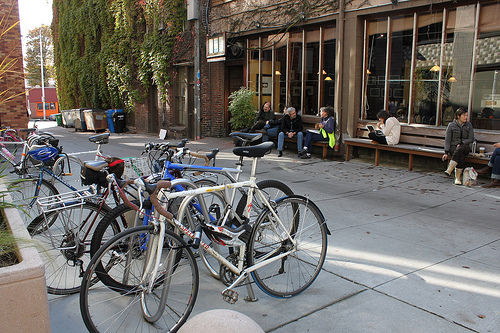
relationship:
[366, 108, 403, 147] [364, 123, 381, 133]
people with laptop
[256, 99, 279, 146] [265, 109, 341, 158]
people on bench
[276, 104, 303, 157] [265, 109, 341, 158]
people on bench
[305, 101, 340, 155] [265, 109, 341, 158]
people on bench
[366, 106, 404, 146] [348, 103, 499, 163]
people on bench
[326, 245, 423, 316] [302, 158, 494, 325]
crack on sidewalk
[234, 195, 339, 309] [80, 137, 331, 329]
wheel on bike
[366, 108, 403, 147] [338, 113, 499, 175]
people on bench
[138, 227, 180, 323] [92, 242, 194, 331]
bike rack behind spokes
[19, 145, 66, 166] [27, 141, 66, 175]
helmet on handle bars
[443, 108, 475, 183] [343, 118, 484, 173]
person on bench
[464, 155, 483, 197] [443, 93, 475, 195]
bag next to person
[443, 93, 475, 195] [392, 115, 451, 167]
person on bench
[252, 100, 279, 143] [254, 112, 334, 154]
people on bench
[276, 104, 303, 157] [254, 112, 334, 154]
people on bench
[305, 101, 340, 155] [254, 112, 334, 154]
people on bench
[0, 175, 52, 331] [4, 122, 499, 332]
concrete planter on sidewalk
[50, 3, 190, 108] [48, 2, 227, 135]
ivy growing up wall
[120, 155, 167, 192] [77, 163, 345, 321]
basket on bike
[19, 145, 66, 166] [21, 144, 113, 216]
helmet on bicycle